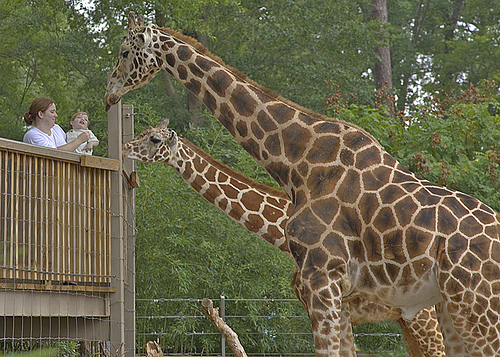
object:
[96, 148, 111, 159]
food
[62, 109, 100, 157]
baby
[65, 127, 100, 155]
shirt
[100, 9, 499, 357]
giraffe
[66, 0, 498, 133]
sky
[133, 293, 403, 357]
fence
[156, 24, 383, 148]
hair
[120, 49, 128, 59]
eye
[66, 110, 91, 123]
hair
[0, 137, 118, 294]
fence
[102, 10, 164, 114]
head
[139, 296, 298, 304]
barbed wire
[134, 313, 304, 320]
barbed wire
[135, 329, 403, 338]
barbed wire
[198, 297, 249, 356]
tree branch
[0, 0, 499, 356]
pen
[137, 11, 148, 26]
horn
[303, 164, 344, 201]
spots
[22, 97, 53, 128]
hair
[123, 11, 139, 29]
horn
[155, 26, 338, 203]
neck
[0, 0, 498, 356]
tree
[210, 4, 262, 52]
tree branch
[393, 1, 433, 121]
tree branch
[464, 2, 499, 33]
tree branch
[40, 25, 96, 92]
tree branch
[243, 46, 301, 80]
tree branch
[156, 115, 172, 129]
horn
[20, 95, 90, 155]
mother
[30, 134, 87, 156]
arm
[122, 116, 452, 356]
giraffe